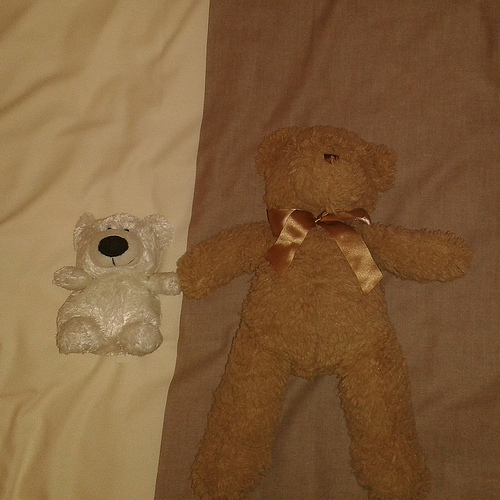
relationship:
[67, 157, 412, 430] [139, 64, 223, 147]
bears on bed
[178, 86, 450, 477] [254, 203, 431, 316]
bear has bow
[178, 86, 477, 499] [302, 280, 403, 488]
bear has leg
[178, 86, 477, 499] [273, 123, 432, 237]
bear has nose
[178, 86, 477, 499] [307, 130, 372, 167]
bear has nose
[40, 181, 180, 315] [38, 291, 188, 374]
bear has legs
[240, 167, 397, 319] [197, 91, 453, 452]
bow on bear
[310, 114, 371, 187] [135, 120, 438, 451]
nose on bear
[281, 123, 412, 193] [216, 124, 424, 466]
eyes on bear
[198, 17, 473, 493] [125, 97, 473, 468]
fabric under bear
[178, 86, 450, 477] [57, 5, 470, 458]
bear on blanket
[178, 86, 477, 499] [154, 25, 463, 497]
bear on blanket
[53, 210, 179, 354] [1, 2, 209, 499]
bear toy on blanket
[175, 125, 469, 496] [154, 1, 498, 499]
bear toy on blanket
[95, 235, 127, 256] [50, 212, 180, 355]
bear nose on bear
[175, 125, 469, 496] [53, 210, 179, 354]
bear toy laying beside bear toy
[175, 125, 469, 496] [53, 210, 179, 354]
bear toy holding hands with bear toy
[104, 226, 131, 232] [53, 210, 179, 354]
eyes on bear toy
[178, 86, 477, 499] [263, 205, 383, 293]
bear with ribbon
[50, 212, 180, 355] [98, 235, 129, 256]
bear with nose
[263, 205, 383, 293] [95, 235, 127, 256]
ribbon on bear nose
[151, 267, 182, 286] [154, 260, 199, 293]
limb on animal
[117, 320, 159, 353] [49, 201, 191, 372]
limb on animal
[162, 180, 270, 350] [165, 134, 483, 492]
arm on animal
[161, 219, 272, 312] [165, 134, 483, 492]
limb on animal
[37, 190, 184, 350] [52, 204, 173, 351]
nose on bear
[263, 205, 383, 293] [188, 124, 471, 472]
ribbon tied bear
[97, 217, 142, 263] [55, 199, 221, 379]
nose on bear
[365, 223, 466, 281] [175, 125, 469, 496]
limb on bear toy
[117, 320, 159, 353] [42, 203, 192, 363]
limb on animal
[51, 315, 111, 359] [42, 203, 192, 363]
limb on animal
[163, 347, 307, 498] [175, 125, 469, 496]
leg of bear toy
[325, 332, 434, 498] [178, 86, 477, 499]
leg of bear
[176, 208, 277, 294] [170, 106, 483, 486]
arm of bear